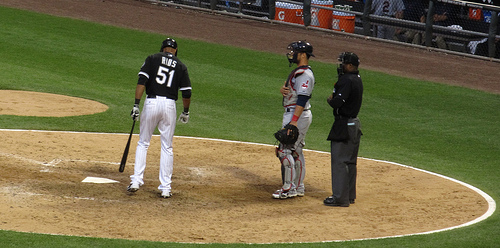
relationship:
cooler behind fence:
[331, 4, 357, 35] [159, 0, 499, 62]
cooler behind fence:
[309, 0, 332, 31] [159, 0, 499, 62]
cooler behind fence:
[273, 0, 305, 26] [159, 0, 499, 62]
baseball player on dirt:
[323, 51, 363, 207] [1, 121, 493, 246]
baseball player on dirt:
[271, 40, 316, 199] [1, 121, 493, 246]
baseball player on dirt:
[126, 37, 192, 198] [1, 121, 493, 246]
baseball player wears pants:
[271, 40, 316, 199] [275, 105, 312, 189]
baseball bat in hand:
[118, 120, 135, 172] [131, 106, 139, 118]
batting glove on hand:
[177, 109, 190, 125] [125, 102, 143, 120]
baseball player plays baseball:
[119, 36, 195, 203] [114, 15, 375, 215]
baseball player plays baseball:
[267, 38, 316, 203] [114, 15, 375, 215]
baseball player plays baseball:
[323, 46, 363, 206] [114, 15, 375, 215]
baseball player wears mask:
[271, 40, 316, 199] [284, 42, 301, 65]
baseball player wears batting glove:
[126, 37, 192, 198] [178, 112, 190, 124]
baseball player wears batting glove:
[126, 37, 192, 198] [130, 104, 140, 121]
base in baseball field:
[81, 177, 120, 184] [1, 3, 498, 246]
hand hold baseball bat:
[130, 102, 140, 125] [111, 108, 137, 181]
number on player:
[148, 69, 208, 106] [119, 33, 224, 183]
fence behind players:
[283, 5, 442, 39] [235, 29, 403, 214]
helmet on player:
[158, 35, 178, 54] [124, 35, 191, 197]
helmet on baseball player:
[285, 37, 316, 65] [271, 40, 316, 199]